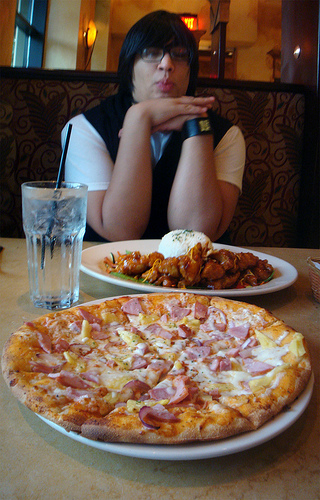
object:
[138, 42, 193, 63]
glasses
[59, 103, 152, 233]
arm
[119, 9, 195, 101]
head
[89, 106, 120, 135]
vest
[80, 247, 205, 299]
dish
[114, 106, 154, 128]
wrist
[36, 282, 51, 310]
glass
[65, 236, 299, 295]
plate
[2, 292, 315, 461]
plate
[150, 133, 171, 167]
tie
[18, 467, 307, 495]
table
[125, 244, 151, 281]
food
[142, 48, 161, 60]
eye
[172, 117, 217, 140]
wrist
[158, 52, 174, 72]
nose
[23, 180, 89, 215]
glass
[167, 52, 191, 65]
eye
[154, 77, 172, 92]
mouth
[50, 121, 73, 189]
straw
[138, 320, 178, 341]
ham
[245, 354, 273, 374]
ham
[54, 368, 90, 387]
ham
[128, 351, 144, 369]
ham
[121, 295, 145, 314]
ham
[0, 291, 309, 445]
pizza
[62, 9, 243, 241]
person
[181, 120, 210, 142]
band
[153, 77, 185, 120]
up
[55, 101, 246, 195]
shirt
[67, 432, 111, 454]
ceramic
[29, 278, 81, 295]
water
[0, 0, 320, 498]
picture